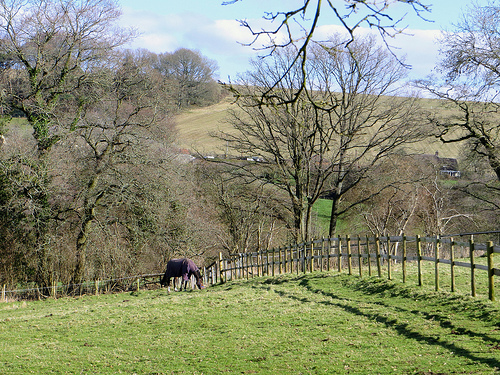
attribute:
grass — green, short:
[19, 264, 497, 373]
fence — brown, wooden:
[187, 228, 493, 300]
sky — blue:
[3, 2, 497, 89]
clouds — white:
[184, 17, 478, 57]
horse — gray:
[162, 258, 205, 293]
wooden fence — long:
[193, 240, 499, 302]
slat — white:
[207, 258, 215, 280]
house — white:
[407, 154, 462, 181]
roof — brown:
[382, 151, 457, 171]